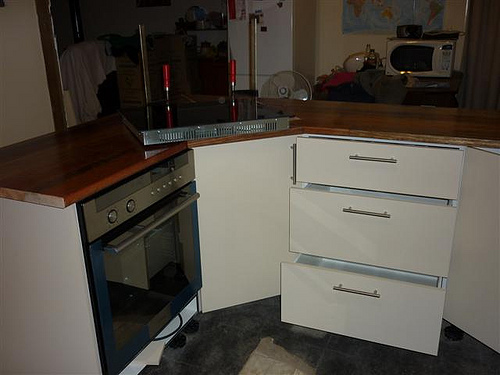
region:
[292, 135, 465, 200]
The smallest white drawer in the counter.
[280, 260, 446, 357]
The biggest drawer is empty.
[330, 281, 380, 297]
A metallic handle in a drawer.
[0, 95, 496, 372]
A nice counter with a wooden surface.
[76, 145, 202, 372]
A nice modern oven.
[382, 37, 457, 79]
A modern microwave is in the background.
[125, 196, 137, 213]
One of the buttons of the oven.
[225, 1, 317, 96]
A refrigerator is in the kitchen.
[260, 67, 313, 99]
A white fan is standing on the floor.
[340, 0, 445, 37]
The drawing of a world map.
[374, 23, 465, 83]
a black and white microwave on counter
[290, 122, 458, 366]
three white drawers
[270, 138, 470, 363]
three drawers that are open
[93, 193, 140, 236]
two dials on a stove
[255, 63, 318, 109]
a small white fan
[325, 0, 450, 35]
the bottom half of a map on the wall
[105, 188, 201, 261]
the handle of an oven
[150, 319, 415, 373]
gray and white tiles on the floor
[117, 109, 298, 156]
a silver grate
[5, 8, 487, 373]
a very clean kitchen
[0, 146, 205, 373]
An oven with a glass front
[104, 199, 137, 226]
A pair of dials for an oven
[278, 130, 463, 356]
A three tier cabinet for storing kitchen goods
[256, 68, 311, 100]
A small desk fan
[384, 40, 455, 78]
A microwave on a table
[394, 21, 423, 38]
A black cooking pot on a microwave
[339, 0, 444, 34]
A poster of the world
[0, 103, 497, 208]
A brown wooden countertop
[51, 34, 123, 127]
A white sheet draped over furniture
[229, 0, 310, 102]
A white refrigerator in the back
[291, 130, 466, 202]
white top drawer in counter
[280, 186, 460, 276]
middle drawer of counter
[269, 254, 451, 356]
bottom drawer of counter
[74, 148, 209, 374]
black oven under counter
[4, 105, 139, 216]
wooden counter over oven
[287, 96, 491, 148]
wooden counter over drawer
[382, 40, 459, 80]
micro wave oven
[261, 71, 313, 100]
top of white fan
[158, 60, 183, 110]
red handle behind counter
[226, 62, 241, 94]
red handle behind counter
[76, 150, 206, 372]
a black built in oven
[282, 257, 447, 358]
a white cabinet drawer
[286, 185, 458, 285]
a white cabinet drawer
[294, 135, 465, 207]
a white cabinet drawer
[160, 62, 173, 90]
a red candle stick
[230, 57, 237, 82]
a red candle stick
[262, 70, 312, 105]
a large white fan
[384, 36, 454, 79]
a white microwave oven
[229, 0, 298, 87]
a white refrigerator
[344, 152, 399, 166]
a metal drawer pull